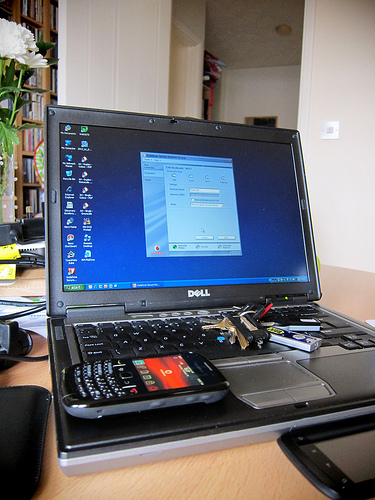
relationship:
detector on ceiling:
[277, 17, 300, 34] [206, 6, 311, 102]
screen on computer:
[89, 145, 278, 270] [44, 105, 375, 467]